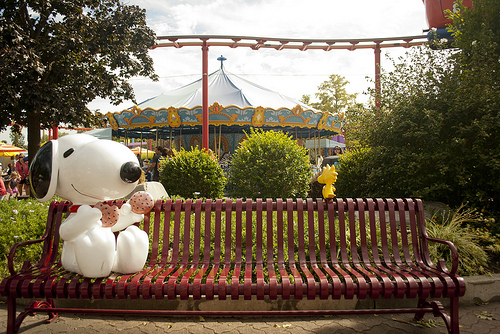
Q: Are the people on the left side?
A: Yes, the people are on the left of the image.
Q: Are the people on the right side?
A: No, the people are on the left of the image.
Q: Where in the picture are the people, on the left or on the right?
A: The people are on the left of the image.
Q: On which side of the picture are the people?
A: The people are on the left of the image.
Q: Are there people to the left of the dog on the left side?
A: Yes, there are people to the left of the dog.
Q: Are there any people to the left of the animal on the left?
A: Yes, there are people to the left of the dog.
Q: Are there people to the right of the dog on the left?
A: No, the people are to the left of the dog.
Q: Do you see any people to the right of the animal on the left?
A: No, the people are to the left of the dog.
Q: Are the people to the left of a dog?
A: Yes, the people are to the left of a dog.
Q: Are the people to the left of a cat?
A: No, the people are to the left of a dog.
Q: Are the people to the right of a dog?
A: No, the people are to the left of a dog.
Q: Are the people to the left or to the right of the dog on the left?
A: The people are to the left of the dog.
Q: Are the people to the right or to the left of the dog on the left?
A: The people are to the left of the dog.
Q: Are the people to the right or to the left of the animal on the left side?
A: The people are to the left of the dog.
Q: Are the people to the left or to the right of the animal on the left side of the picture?
A: The people are to the left of the dog.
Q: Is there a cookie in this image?
A: Yes, there is a cookie.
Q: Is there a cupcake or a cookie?
A: Yes, there is a cookie.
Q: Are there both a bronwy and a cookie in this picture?
A: No, there is a cookie but no brownies.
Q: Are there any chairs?
A: No, there are no chairs.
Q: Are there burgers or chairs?
A: No, there are no chairs or burgers.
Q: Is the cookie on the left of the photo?
A: Yes, the cookie is on the left of the image.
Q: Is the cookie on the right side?
A: No, the cookie is on the left of the image.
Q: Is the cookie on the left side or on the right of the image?
A: The cookie is on the left of the image.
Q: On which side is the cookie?
A: The cookie is on the left of the image.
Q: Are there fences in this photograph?
A: No, there are no fences.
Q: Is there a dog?
A: Yes, there is a dog.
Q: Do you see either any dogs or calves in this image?
A: Yes, there is a dog.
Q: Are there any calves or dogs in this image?
A: Yes, there is a dog.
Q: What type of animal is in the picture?
A: The animal is a dog.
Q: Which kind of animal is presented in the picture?
A: The animal is a dog.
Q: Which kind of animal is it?
A: The animal is a dog.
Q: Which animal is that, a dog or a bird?
A: This is a dog.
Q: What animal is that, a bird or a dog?
A: This is a dog.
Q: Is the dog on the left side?
A: Yes, the dog is on the left of the image.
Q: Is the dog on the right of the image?
A: No, the dog is on the left of the image.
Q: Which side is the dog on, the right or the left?
A: The dog is on the left of the image.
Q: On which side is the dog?
A: The dog is on the left of the image.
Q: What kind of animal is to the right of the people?
A: The animal is a dog.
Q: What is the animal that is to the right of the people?
A: The animal is a dog.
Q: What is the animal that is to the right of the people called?
A: The animal is a dog.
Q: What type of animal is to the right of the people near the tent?
A: The animal is a dog.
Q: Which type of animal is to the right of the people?
A: The animal is a dog.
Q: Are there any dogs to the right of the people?
A: Yes, there is a dog to the right of the people.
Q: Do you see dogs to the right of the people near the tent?
A: Yes, there is a dog to the right of the people.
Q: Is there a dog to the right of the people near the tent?
A: Yes, there is a dog to the right of the people.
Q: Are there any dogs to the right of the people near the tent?
A: Yes, there is a dog to the right of the people.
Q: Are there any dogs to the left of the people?
A: No, the dog is to the right of the people.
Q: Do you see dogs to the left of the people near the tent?
A: No, the dog is to the right of the people.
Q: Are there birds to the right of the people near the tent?
A: No, there is a dog to the right of the people.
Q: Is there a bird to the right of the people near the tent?
A: No, there is a dog to the right of the people.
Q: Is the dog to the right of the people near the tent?
A: Yes, the dog is to the right of the people.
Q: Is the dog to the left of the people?
A: No, the dog is to the right of the people.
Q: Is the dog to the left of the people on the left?
A: No, the dog is to the right of the people.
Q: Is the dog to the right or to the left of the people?
A: The dog is to the right of the people.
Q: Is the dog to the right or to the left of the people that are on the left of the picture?
A: The dog is to the right of the people.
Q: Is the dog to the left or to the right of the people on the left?
A: The dog is to the right of the people.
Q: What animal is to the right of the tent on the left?
A: The animal is a dog.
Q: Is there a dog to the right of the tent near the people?
A: Yes, there is a dog to the right of the tent.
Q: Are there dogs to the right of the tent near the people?
A: Yes, there is a dog to the right of the tent.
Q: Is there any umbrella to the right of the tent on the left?
A: No, there is a dog to the right of the tent.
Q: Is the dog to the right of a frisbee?
A: No, the dog is to the right of the tent.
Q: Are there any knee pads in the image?
A: No, there are no knee pads.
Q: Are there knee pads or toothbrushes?
A: No, there are no knee pads or toothbrushes.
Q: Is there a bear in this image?
A: No, there are no bears.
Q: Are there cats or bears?
A: No, there are no bears or cats.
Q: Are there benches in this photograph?
A: Yes, there is a bench.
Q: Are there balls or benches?
A: Yes, there is a bench.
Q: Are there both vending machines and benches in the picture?
A: No, there is a bench but no vending machines.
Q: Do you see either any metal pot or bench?
A: Yes, there is a metal bench.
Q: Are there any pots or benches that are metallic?
A: Yes, the bench is metallic.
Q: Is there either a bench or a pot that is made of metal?
A: Yes, the bench is made of metal.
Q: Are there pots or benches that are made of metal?
A: Yes, the bench is made of metal.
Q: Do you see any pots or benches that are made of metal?
A: Yes, the bench is made of metal.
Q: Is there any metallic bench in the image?
A: Yes, there is a metal bench.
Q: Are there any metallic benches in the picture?
A: Yes, there is a metal bench.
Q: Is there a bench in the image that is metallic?
A: Yes, there is a bench that is metallic.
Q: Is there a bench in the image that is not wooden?
A: Yes, there is a metallic bench.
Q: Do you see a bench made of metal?
A: Yes, there is a bench that is made of metal.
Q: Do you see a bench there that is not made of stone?
A: Yes, there is a bench that is made of metal.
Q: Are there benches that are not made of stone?
A: Yes, there is a bench that is made of metal.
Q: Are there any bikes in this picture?
A: No, there are no bikes.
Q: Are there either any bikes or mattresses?
A: No, there are no bikes or mattresses.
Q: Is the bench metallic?
A: Yes, the bench is metallic.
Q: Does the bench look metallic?
A: Yes, the bench is metallic.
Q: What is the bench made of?
A: The bench is made of metal.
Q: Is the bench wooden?
A: No, the bench is metallic.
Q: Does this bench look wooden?
A: No, the bench is metallic.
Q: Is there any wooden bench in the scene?
A: No, there is a bench but it is metallic.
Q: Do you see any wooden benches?
A: No, there is a bench but it is metallic.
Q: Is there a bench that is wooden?
A: No, there is a bench but it is metallic.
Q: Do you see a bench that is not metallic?
A: No, there is a bench but it is metallic.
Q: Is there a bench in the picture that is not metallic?
A: No, there is a bench but it is metallic.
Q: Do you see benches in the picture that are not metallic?
A: No, there is a bench but it is metallic.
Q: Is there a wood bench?
A: No, there is a bench but it is made of metal.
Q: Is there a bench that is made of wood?
A: No, there is a bench but it is made of metal.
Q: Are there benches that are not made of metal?
A: No, there is a bench but it is made of metal.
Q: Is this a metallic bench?
A: Yes, this is a metallic bench.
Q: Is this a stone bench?
A: No, this is a metallic bench.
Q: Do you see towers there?
A: No, there are no towers.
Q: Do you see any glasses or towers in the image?
A: No, there are no towers or glasses.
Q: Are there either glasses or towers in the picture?
A: No, there are no towers or glasses.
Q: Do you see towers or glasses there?
A: No, there are no towers or glasses.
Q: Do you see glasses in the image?
A: No, there are no glasses.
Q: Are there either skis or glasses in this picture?
A: No, there are no glasses or skis.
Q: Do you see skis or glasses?
A: No, there are no glasses or skis.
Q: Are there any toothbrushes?
A: No, there are no toothbrushes.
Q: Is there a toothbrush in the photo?
A: No, there are no toothbrushes.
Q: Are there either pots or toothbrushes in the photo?
A: No, there are no toothbrushes or pots.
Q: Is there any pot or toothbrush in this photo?
A: No, there are no toothbrushes or pots.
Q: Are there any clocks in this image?
A: No, there are no clocks.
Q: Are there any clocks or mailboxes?
A: No, there are no clocks or mailboxes.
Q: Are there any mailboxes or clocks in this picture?
A: No, there are no clocks or mailboxes.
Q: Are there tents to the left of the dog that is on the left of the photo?
A: Yes, there is a tent to the left of the dog.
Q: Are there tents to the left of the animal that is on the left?
A: Yes, there is a tent to the left of the dog.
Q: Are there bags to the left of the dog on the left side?
A: No, there is a tent to the left of the dog.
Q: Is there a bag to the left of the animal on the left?
A: No, there is a tent to the left of the dog.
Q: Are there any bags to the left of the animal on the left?
A: No, there is a tent to the left of the dog.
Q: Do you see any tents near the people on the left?
A: Yes, there is a tent near the people.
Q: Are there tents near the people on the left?
A: Yes, there is a tent near the people.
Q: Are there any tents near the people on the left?
A: Yes, there is a tent near the people.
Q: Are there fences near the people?
A: No, there is a tent near the people.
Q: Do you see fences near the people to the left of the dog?
A: No, there is a tent near the people.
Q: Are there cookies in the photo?
A: Yes, there are cookies.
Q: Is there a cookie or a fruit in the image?
A: Yes, there are cookies.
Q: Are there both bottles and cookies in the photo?
A: No, there are cookies but no bottles.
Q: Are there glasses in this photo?
A: No, there are no glasses.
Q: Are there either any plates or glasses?
A: No, there are no glasses or plates.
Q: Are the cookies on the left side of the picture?
A: Yes, the cookies are on the left of the image.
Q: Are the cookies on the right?
A: No, the cookies are on the left of the image.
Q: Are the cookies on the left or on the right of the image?
A: The cookies are on the left of the image.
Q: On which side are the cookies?
A: The cookies are on the left of the image.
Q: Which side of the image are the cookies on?
A: The cookies are on the left of the image.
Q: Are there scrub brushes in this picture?
A: No, there are no scrub brushes.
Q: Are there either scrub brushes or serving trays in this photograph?
A: No, there are no scrub brushes or serving trays.